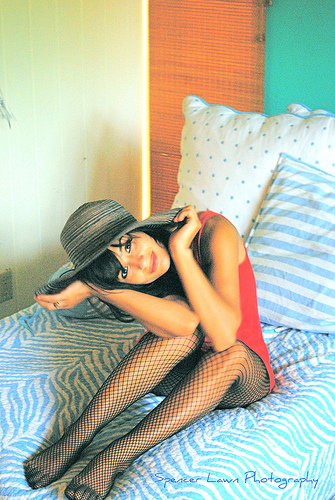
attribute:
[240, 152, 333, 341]
blue pillow — white, striped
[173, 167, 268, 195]
pillow case — white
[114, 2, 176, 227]
corner — brightly lit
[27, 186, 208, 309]
hat — gray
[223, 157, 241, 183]
dots — blue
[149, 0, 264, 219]
blind — wood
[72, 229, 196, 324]
hair — black